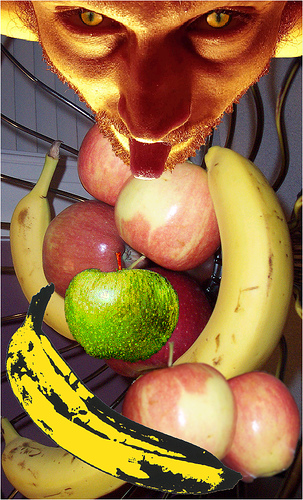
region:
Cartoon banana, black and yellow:
[2, 286, 245, 496]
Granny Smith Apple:
[70, 261, 180, 360]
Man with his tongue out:
[18, 0, 300, 183]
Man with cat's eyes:
[52, 0, 255, 41]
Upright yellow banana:
[192, 152, 298, 377]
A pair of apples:
[126, 363, 296, 481]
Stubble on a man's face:
[61, 96, 244, 195]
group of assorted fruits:
[23, 143, 292, 488]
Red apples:
[21, 106, 224, 280]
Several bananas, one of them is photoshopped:
[1, 261, 69, 498]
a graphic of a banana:
[2, 284, 248, 490]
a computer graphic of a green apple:
[65, 253, 178, 363]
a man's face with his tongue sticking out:
[34, 1, 288, 184]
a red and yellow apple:
[118, 340, 239, 463]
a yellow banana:
[2, 413, 140, 498]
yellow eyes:
[61, 2, 250, 36]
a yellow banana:
[173, 145, 294, 377]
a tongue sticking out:
[119, 132, 173, 182]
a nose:
[100, 49, 198, 145]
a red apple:
[41, 195, 181, 305]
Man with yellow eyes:
[204, 10, 229, 25]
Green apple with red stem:
[62, 254, 177, 360]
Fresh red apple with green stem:
[120, 363, 235, 459]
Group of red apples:
[53, 174, 191, 258]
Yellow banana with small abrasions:
[216, 145, 293, 365]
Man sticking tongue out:
[119, 130, 180, 178]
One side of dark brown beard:
[84, 84, 119, 148]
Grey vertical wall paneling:
[11, 88, 58, 127]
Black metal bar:
[28, 68, 51, 99]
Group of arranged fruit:
[24, 198, 267, 316]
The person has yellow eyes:
[62, 2, 265, 40]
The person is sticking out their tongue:
[21, 2, 280, 182]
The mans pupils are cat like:
[44, 2, 254, 43]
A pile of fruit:
[14, 104, 274, 487]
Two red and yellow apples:
[137, 357, 295, 482]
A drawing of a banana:
[11, 284, 241, 496]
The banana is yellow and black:
[10, 281, 200, 489]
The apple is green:
[63, 263, 179, 368]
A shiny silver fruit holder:
[4, 42, 87, 225]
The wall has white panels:
[3, 42, 93, 209]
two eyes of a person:
[66, 1, 253, 29]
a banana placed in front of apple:
[4, 315, 240, 487]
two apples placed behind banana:
[146, 361, 280, 446]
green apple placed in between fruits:
[74, 257, 180, 353]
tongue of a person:
[127, 135, 178, 178]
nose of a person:
[110, 65, 197, 141]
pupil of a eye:
[211, 12, 226, 21]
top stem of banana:
[24, 146, 69, 197]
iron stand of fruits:
[268, 77, 293, 185]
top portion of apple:
[108, 249, 124, 268]